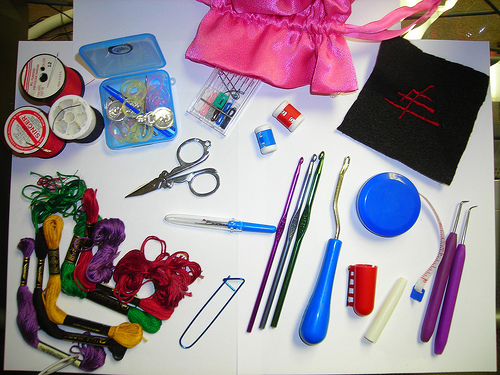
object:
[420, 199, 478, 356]
hooks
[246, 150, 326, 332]
hooks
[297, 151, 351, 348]
hooks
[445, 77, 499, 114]
wall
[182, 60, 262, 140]
sewing kit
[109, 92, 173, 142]
buttons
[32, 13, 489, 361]
sewing kit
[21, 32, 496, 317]
table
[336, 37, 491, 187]
bag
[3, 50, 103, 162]
spools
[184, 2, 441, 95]
clothe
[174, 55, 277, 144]
case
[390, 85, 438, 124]
red stitching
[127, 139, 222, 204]
scissors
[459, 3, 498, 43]
table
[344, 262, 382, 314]
redthimble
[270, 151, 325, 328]
crochet needle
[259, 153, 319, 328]
crochet needle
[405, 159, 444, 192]
ground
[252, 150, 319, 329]
crochet needle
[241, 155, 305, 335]
crochet needle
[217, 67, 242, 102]
pin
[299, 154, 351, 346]
hook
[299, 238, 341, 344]
handle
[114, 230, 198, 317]
string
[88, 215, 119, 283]
string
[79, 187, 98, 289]
string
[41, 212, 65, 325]
string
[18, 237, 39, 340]
string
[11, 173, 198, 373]
string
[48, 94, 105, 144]
spool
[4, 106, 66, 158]
spool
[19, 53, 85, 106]
spool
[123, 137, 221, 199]
metal scissors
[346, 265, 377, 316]
thimble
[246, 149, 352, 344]
needles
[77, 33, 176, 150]
box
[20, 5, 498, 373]
table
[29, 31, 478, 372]
container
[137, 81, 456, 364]
table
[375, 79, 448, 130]
writing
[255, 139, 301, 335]
hooks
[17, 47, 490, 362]
craft supplies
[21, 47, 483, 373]
table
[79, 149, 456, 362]
table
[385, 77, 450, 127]
japanese letters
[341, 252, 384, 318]
thimble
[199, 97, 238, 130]
needles